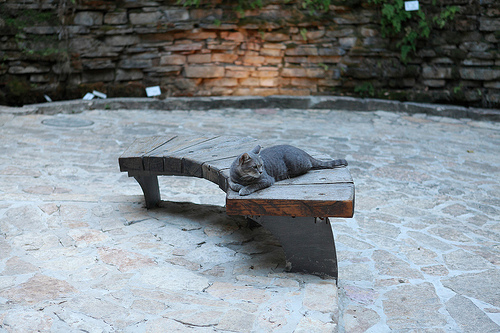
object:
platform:
[113, 120, 371, 276]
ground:
[1, 90, 494, 331]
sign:
[145, 86, 162, 96]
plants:
[22, 42, 71, 62]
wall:
[4, 2, 499, 115]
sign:
[406, 0, 418, 10]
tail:
[320, 158, 349, 169]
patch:
[163, 31, 344, 101]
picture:
[3, 5, 497, 332]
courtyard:
[7, 2, 494, 330]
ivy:
[385, 3, 426, 58]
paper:
[92, 90, 107, 99]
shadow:
[210, 215, 262, 269]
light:
[184, 28, 295, 98]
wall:
[37, 11, 464, 103]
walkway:
[366, 123, 497, 283]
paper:
[404, 0, 420, 12]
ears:
[240, 152, 252, 164]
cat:
[229, 144, 349, 196]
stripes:
[309, 159, 348, 170]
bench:
[118, 130, 359, 282]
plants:
[433, 3, 459, 25]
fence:
[0, 0, 499, 103]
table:
[117, 122, 358, 282]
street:
[357, 134, 479, 322]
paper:
[145, 86, 162, 97]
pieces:
[145, 85, 162, 97]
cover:
[40, 115, 95, 127]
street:
[10, 130, 115, 325]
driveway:
[358, 137, 480, 311]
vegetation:
[285, 0, 340, 20]